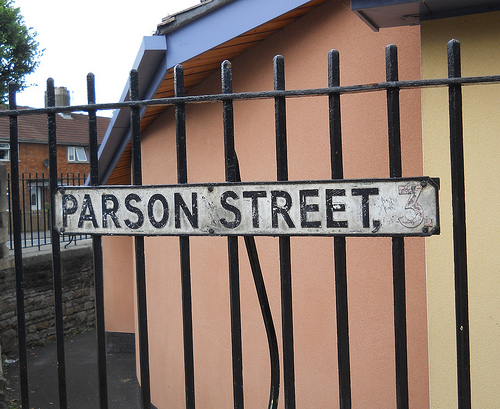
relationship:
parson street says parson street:
[62, 187, 379, 229] [62, 187, 379, 229]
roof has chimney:
[1, 102, 112, 146] [45, 86, 70, 111]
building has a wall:
[97, 0, 428, 407] [102, 3, 426, 408]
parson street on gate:
[62, 187, 379, 229] [3, 38, 497, 405]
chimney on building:
[45, 86, 70, 111] [0, 104, 112, 236]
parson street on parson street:
[62, 187, 379, 229] [62, 187, 379, 229]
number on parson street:
[396, 185, 425, 230] [62, 187, 379, 229]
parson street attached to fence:
[62, 187, 379, 229] [3, 38, 497, 405]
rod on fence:
[8, 79, 33, 408] [3, 38, 497, 405]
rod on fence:
[445, 38, 473, 405] [3, 38, 497, 405]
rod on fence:
[221, 58, 250, 408] [3, 38, 497, 405]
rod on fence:
[46, 77, 70, 408] [3, 38, 497, 405]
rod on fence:
[86, 73, 110, 408] [3, 38, 497, 405]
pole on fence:
[2, 75, 498, 117] [3, 38, 497, 405]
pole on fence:
[0, 176, 87, 184] [1, 172, 94, 252]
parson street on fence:
[62, 187, 379, 229] [3, 38, 497, 405]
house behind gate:
[97, 0, 428, 407] [3, 38, 497, 405]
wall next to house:
[419, 9, 499, 408] [97, 0, 428, 407]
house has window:
[0, 104, 112, 236] [68, 146, 75, 161]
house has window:
[0, 104, 112, 236] [74, 146, 87, 162]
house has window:
[0, 104, 112, 236] [1, 144, 11, 162]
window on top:
[68, 146, 75, 161] [1, 103, 100, 176]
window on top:
[74, 146, 87, 162] [1, 103, 100, 176]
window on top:
[1, 144, 11, 162] [1, 103, 100, 176]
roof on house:
[1, 102, 112, 146] [0, 104, 112, 236]